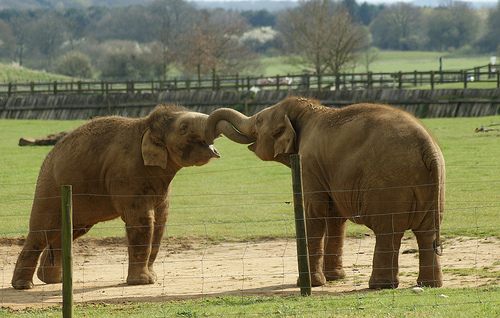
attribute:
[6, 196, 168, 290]
legs — back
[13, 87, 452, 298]
elephants — playing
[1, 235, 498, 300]
patch — brown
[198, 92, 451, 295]
elephant — joyous, facing, brown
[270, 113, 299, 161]
elephant ear — tiny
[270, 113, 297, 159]
ear — small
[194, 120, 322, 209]
mouths — open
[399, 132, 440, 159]
ground — grass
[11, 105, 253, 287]
elephant — smiling, playing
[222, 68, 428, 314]
elephant — greeting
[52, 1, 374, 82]
trees — background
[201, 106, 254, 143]
trunk — curled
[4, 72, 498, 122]
fence — long, grey, slatted, closed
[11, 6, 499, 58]
trees — several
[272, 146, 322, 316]
fence post — wooden